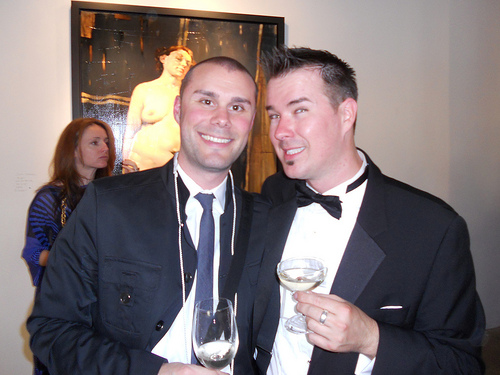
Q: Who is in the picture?
A: Two men.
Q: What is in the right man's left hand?
A: Martini glass.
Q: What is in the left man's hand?
A: Wine glass.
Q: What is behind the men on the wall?
A: Painting.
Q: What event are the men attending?
A: Art opening.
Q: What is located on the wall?
A: The painting.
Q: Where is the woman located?
A: She is next to the painting.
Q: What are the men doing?
A: Celebrating.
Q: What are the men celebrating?
A: A wedding.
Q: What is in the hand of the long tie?
A: A wine glass.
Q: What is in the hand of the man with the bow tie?
A: A champagne glass.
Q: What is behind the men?
A: A photo.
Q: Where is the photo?
A: On a wall.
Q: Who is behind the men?
A: A woman.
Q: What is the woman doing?
A: Standing still.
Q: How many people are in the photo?
A: Three.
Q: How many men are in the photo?
A: Two.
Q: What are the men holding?
A: Glasses.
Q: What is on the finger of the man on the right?
A: A ring.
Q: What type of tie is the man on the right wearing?
A: A bow tie.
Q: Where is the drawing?
A: On the wall behind the men.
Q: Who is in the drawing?
A: A naked woman.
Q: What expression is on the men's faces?
A: Smiles.